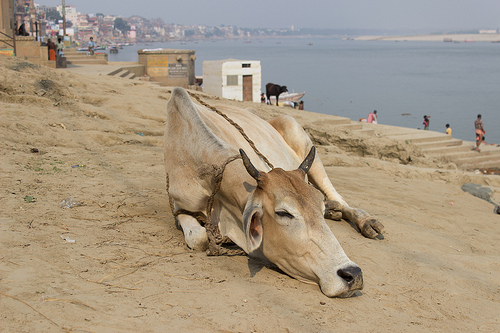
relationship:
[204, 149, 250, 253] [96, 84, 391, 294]
neck of cow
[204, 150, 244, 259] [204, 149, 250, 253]
rope around neck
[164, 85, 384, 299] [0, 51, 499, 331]
animal laying in dirt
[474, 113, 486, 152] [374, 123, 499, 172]
person standing on steps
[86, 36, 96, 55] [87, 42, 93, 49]
person wearing light shirt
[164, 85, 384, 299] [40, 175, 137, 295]
animal laying on dirt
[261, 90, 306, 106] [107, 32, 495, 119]
boat in water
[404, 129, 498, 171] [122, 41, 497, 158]
steps leading down to water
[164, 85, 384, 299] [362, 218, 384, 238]
animal has hoof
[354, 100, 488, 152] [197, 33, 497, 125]
people near water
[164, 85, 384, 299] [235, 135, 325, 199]
animal with horns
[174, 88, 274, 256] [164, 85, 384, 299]
rope on animal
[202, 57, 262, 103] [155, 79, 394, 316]
building behind cow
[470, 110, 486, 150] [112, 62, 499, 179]
person at river bank